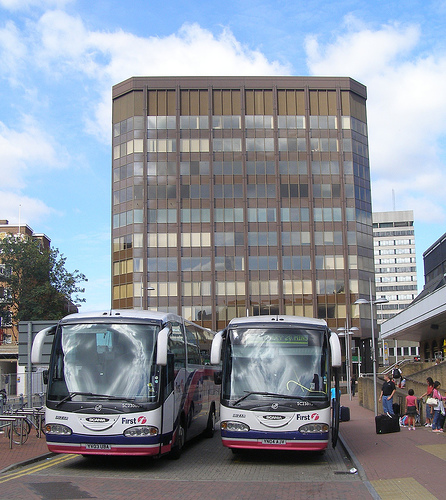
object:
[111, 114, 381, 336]
windows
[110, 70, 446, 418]
building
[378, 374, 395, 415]
people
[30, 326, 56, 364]
mirror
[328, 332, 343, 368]
mirror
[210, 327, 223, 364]
mirror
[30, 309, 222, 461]
bus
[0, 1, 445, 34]
blue sky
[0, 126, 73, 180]
white cloud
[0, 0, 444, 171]
cloud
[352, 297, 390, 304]
streetlights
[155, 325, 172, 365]
mirror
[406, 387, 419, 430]
person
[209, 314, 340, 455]
bus